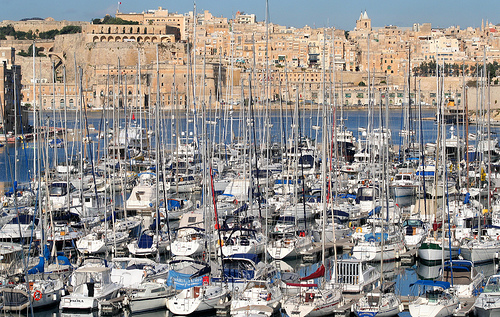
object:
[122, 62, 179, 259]
ships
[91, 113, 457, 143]
sea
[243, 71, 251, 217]
poles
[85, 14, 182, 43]
building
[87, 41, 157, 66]
wall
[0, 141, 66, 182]
water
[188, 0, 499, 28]
sky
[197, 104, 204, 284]
masts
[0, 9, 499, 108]
land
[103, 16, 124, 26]
trees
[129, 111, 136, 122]
buoy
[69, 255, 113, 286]
tender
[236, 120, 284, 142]
harbor